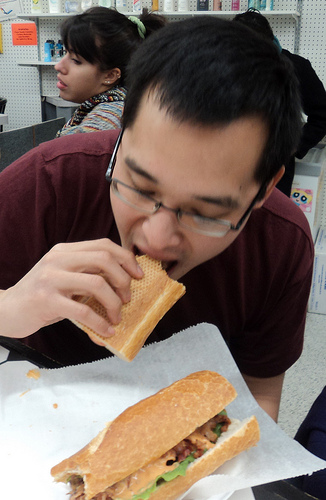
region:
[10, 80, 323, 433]
the man is eating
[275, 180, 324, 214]
cartoon's hair is yellow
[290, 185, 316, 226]
cartoon's hair is yellow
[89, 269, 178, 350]
part of sandwhich being eaten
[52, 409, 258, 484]
large portion of sandwhich left uneaten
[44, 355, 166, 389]
white parchment paper for wrapping food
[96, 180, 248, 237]
black framed glasses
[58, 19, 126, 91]
Woman with her eyes closed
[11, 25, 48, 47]
orange sign on pegboard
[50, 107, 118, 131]
coorful sweater on woman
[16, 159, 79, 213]
burgandy colored t shirt on man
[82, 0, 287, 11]
shelf with multple toiletries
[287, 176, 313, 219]
graphic cartoon picture of a kitten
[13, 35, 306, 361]
A man wearing a red shirt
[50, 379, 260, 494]
A sandwich on white paper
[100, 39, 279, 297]
The man has black glasses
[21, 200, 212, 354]
The man is holding half a sandwich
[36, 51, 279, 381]
The man is taking a bite of a sandwich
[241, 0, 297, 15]
Light blue and white bottle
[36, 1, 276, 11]
Many bottles on a white shelf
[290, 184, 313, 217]
Pink Powder Puff Girl sticker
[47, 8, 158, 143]
Woman with black hair tied up in a ponytail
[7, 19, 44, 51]
Orange sign with black writing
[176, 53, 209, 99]
part of some hair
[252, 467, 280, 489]
edge of a paper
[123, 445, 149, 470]
part of a bread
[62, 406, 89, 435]
part of a paper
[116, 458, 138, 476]
edge of a bread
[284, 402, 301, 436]
part of a floor